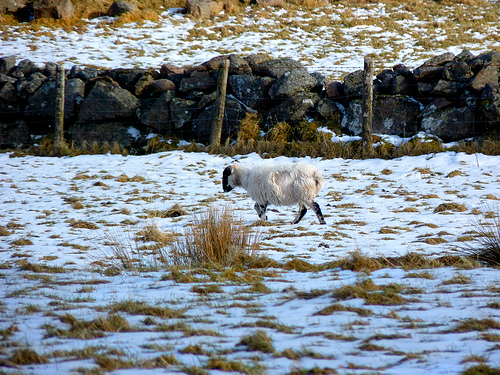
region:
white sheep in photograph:
[200, 135, 370, 243]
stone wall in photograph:
[30, 18, 498, 116]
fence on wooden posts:
[30, 54, 432, 164]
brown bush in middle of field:
[162, 184, 273, 295]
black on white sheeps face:
[212, 154, 246, 211]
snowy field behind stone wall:
[30, 15, 484, 63]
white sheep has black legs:
[251, 191, 335, 231]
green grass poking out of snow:
[52, 164, 332, 374]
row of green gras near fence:
[22, 135, 449, 167]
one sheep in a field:
[201, 130, 462, 292]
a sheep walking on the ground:
[194, 120, 376, 261]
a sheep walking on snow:
[179, 157, 319, 277]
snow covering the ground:
[51, 177, 276, 367]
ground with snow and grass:
[32, 175, 166, 352]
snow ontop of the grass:
[2, 212, 185, 349]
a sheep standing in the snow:
[217, 160, 386, 270]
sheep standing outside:
[143, 110, 408, 313]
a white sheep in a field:
[204, 120, 424, 327]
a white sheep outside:
[193, 134, 413, 289]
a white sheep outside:
[128, 92, 438, 323]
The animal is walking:
[211, 157, 342, 222]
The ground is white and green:
[66, 269, 193, 360]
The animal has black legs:
[253, 190, 428, 248]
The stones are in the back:
[123, 56, 399, 158]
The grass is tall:
[178, 201, 297, 326]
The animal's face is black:
[207, 154, 247, 219]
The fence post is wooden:
[205, 62, 270, 163]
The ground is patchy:
[122, 10, 352, 105]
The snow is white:
[264, 307, 326, 369]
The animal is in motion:
[187, 142, 392, 234]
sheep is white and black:
[193, 151, 387, 260]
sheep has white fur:
[220, 129, 320, 227]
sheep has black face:
[217, 174, 239, 197]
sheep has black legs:
[248, 191, 339, 232]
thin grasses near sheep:
[121, 192, 254, 274]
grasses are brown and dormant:
[125, 191, 263, 278]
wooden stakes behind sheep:
[10, 57, 465, 147]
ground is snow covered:
[23, 157, 496, 344]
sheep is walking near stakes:
[209, 158, 356, 250]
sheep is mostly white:
[218, 143, 345, 234]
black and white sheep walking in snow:
[225, 164, 320, 216]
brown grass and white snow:
[10, 283, 177, 361]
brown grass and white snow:
[177, 247, 456, 362]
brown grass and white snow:
[9, 165, 201, 293]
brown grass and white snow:
[343, 152, 480, 252]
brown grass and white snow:
[12, 2, 150, 57]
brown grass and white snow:
[176, 5, 492, 45]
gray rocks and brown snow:
[7, 72, 51, 140]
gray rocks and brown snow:
[80, 75, 362, 140]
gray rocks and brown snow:
[388, 68, 485, 128]